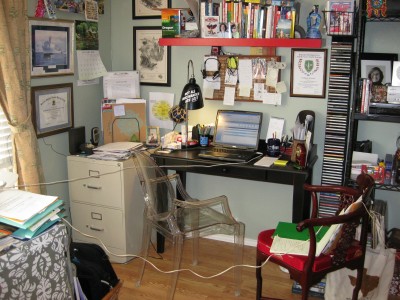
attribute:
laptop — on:
[195, 103, 266, 177]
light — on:
[173, 59, 206, 156]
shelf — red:
[161, 33, 338, 57]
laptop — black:
[195, 103, 274, 175]